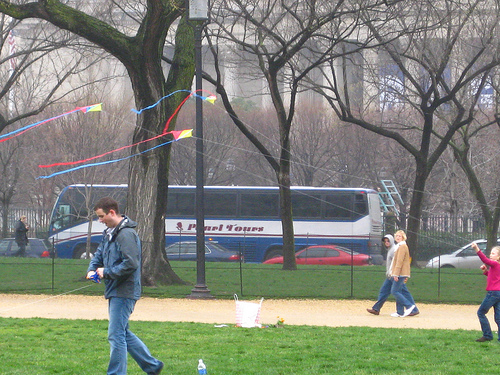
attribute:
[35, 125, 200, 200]
kite — blue 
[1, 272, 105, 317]
string — white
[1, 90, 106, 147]
kite — red, yellow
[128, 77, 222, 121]
kite — yellow, red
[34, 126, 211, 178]
kite — yellow, red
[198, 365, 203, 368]
label — blue 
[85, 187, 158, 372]
black coat — blue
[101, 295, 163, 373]
jean — blue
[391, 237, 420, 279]
shirt — pink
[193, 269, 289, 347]
white bag — white 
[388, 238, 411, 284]
hoodie — gray 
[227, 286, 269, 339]
hand bag — white 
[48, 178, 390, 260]
bus — white 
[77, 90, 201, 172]
kites — blue 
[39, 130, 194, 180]
kite — colorful 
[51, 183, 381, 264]
bus — passing by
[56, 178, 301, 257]
bus — blue, white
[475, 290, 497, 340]
jeans — blue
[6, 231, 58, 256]
hatchback —  black 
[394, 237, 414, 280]
jacket — brown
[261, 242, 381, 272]
car — red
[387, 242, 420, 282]
coat — brown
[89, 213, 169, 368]
clothes — blue 